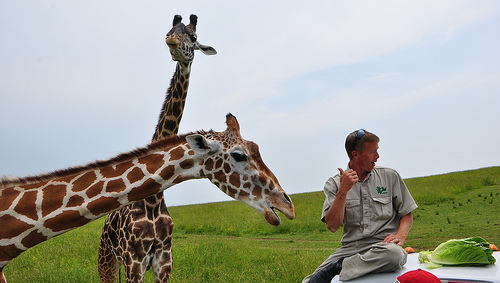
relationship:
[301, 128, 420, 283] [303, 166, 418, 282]
guy wearing a uniform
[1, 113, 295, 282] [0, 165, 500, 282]
giraffe on grass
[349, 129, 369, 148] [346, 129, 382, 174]
glasses are on head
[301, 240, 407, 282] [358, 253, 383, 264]
pants have wrinkle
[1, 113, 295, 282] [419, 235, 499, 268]
giraffe trying to get food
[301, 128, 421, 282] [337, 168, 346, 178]
guy pointing h thumb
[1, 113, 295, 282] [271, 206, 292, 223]
giraffe has mouth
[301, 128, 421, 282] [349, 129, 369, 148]
guy has glasses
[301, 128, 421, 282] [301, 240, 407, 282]
guy has pants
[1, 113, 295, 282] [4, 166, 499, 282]
giraffe in a field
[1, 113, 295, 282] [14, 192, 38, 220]
giraffe has spot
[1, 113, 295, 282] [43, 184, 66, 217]
giraffe has spot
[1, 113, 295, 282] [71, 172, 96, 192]
giraffe has spot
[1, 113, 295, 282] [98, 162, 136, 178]
giraffe has spot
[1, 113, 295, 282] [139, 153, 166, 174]
giraffe has spot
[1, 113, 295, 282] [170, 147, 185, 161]
giraffe has spot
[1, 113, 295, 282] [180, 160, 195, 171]
giraffe has spot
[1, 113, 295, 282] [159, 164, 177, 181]
giraffe has spot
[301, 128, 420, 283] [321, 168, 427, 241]
guy wearing a shirt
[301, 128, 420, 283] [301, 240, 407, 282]
guy wearing pants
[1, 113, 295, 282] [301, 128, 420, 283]
giraffe leaning towards guy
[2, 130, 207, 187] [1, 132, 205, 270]
hair running down neck